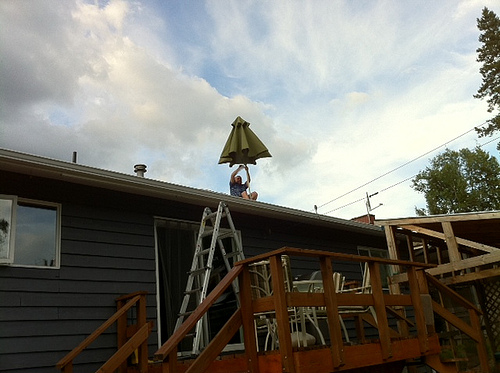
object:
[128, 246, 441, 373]
patio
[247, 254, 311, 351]
outdoor furniture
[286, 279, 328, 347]
outdoor furniture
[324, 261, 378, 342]
outdoor furniture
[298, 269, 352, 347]
outdoor furniture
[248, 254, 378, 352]
furniture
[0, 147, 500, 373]
building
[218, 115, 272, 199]
umbrella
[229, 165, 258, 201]
person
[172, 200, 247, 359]
ladder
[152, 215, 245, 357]
door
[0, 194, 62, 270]
window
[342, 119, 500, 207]
power lines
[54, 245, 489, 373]
deck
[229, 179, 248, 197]
shirt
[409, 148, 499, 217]
tree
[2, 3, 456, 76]
clouds